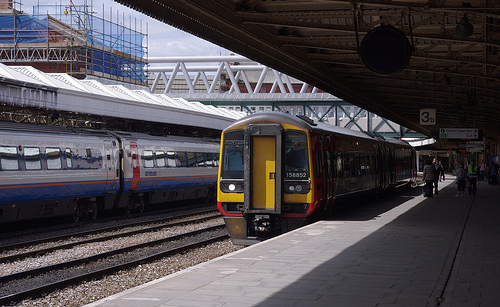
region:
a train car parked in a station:
[210, 108, 419, 243]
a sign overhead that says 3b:
[417, 105, 437, 125]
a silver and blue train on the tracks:
[0, 121, 219, 225]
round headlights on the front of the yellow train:
[225, 183, 302, 193]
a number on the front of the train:
[283, 169, 308, 179]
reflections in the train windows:
[0, 143, 221, 168]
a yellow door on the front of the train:
[247, 133, 278, 209]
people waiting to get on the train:
[412, 148, 479, 200]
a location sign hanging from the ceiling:
[437, 124, 480, 142]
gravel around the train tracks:
[2, 199, 242, 305]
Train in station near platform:
[217, 111, 416, 223]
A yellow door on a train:
[248, 132, 273, 209]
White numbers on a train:
[284, 170, 307, 180]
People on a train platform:
[425, 151, 483, 200]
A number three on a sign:
[417, 107, 438, 127]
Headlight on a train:
[226, 181, 233, 195]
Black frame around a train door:
[240, 119, 284, 211]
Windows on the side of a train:
[4, 144, 71, 169]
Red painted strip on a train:
[127, 139, 146, 186]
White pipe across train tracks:
[147, 54, 268, 62]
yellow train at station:
[233, 104, 417, 218]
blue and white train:
[13, 138, 218, 190]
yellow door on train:
[240, 112, 289, 239]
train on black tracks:
[45, 190, 236, 305]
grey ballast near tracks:
[13, 221, 219, 305]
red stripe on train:
[110, 122, 153, 197]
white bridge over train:
[146, 39, 329, 100]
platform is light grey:
[281, 242, 445, 297]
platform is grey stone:
[170, 242, 442, 295]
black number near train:
[379, 101, 434, 133]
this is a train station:
[20, 28, 454, 278]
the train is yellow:
[197, 123, 362, 239]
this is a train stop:
[326, 158, 465, 264]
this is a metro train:
[178, 95, 317, 198]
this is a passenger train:
[16, 128, 186, 192]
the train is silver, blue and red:
[5, 137, 115, 205]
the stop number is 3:
[395, 91, 463, 138]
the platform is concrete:
[181, 224, 332, 288]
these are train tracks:
[29, 240, 123, 302]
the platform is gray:
[280, 233, 420, 299]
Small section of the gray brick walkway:
[344, 243, 399, 270]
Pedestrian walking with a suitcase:
[421, 158, 436, 196]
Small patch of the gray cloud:
[168, 42, 183, 54]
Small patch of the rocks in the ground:
[121, 273, 136, 287]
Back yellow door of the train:
[254, 135, 276, 209]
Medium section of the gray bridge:
[178, 54, 231, 92]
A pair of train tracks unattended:
[130, 238, 162, 264]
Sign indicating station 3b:
[418, 107, 437, 127]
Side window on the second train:
[21, 146, 43, 173]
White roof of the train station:
[79, 77, 111, 97]